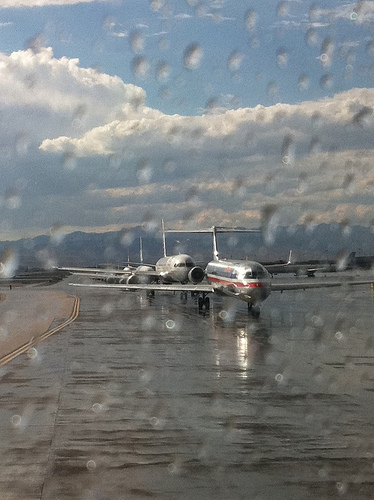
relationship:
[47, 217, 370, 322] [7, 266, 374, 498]
airplanes on road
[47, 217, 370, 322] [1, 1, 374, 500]
airplanes in rain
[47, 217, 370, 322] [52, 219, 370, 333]
airplanes in a line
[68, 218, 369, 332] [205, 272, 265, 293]
airplane has stripe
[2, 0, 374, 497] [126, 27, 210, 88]
window has raindrops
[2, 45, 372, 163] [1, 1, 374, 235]
clouds in sky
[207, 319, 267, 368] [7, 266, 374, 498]
reflection on road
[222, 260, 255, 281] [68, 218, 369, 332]
reflection on airplane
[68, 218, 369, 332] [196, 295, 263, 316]
airplane has landing gear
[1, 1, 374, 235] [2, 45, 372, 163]
sky has clouds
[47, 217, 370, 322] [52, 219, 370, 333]
airplanes are in line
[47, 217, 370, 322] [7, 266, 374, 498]
airplanes are on road